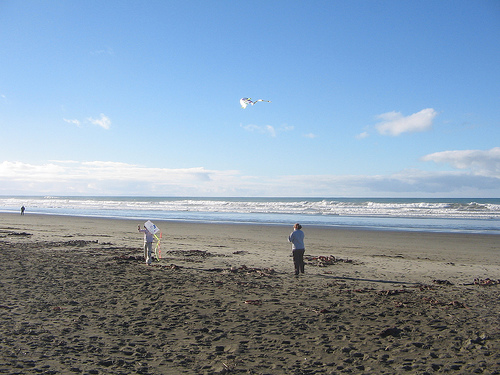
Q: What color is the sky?
A: The sky is blue.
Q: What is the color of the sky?
A: Blue and white.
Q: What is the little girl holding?
A: A kite.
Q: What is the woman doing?
A: Flying a kite.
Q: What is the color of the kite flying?
A: White.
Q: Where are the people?
A: At the beach.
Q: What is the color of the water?
A: Blue.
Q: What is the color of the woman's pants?
A: Black.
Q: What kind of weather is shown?
A: Sunny.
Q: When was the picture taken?
A: It is daytime.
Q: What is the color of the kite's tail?
A: Orange and yellow.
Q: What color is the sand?
A: Light brown.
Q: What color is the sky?
A: Blue.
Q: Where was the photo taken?
A: A beach.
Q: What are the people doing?
A: Flying kites.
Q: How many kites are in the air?
A: One.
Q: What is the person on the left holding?
A: A kite.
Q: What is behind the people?
A: The ocean.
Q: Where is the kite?
A: In the air.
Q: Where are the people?
A: On the beach.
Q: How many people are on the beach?
A: Three.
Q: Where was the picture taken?
A: At the beach.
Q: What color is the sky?
A: Blue.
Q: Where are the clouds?
A: In the sky.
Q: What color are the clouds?
A: White.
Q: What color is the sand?
A: Brown.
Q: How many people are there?
A: Three.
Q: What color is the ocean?
A: Blue and white.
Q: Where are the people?
A: On the sand.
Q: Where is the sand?
A: In front of the ocean.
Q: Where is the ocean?
A: Behind the people.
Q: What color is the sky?
A: Blue and white.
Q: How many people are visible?
A: 3.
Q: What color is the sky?
A: Blue.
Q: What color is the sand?
A: Brown.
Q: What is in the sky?
A: A kite.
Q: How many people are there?
A: Three.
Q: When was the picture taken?
A: Daytime.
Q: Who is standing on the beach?
A: The three people.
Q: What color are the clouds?
A: White.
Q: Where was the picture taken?
A: The beach.